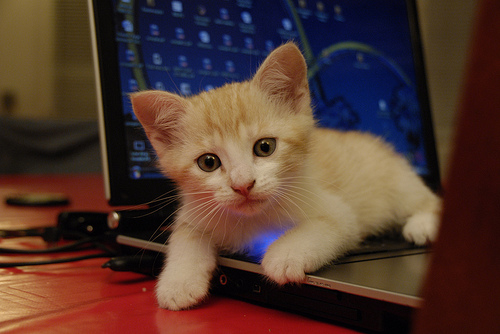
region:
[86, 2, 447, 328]
Kitten sitting on top of laptop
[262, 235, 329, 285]
Cat's paw resting on laptop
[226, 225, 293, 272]
Light shining under cat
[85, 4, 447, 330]
Fluffy white cat laying on computer on table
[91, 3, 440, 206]
Links on screen of computer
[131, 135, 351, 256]
Long whiskers on cat's face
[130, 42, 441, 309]
an image to disarm people who don't like cats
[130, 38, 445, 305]
a sweet tabby kitty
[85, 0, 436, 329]
a laptop with a kitten on top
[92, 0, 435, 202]
the screen of a laptop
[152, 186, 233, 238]
abundant whiskers on the kitty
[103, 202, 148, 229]
the hinge of the laptop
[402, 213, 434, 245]
the back paw of the kitten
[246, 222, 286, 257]
a blue glow from the laptop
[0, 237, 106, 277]
cords from the computer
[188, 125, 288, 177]
eyes of the kitty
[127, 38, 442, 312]
a furry white kitten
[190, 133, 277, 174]
two cute kitten eyes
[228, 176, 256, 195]
a pink cat nose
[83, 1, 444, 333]
a kitten on a laptop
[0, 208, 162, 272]
cables on a red table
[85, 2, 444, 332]
a black and silver laptop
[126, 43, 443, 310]
a kitten with whiskers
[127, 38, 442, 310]
a cute furry kitten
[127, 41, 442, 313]
a kitten with yellow eyes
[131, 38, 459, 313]
A cute little kitten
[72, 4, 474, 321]
An open laptop computer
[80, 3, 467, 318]
A cute little kitten on an open laptop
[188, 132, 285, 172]
The original cat eyes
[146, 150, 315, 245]
A fine set of cat whiskers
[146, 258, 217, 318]
This a cats paw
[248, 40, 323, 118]
An upright cats ear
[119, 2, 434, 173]
a lapto screen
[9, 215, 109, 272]
a laptop cable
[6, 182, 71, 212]
A blurry cell phone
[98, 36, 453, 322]
a white cat in the background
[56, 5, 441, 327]
a cat on the laptop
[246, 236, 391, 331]
a cats paw in he background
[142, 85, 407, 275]
the cats whiskers in the background